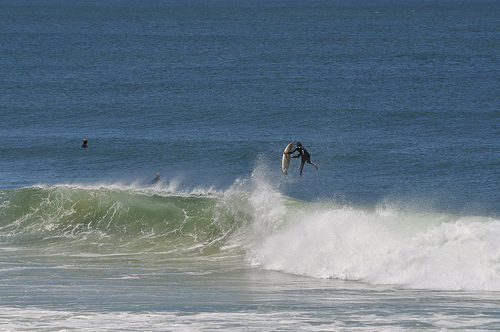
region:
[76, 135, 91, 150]
a person in the ocean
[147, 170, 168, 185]
a person in the ocean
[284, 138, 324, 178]
a person in the air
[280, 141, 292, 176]
a white surfboard in the air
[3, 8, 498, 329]
the ocean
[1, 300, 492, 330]
some sea foam on the water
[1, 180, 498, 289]
A very large wave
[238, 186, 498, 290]
a wave crashing down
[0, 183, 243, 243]
A cresting wave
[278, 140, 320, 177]
a surfer in the air with his board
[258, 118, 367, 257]
Man in mid air with surf board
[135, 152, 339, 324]
Wave is coming to a cap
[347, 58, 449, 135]
The distance of the ocean is flat.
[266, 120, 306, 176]
Man holding a surfboard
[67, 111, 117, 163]
Man in the ocean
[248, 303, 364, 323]
white foam on the water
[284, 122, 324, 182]
Surfers legs are straight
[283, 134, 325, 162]
Man is wearing a wetsuit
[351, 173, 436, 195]
Water is spraying in the air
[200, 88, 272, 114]
Small wave in the ocean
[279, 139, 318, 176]
person on a surf board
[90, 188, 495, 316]
a tidal wave on water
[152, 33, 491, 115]
clear body of water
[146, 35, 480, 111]
body of ocean water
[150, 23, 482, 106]
body of sea salt water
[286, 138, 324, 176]
person in a wet suit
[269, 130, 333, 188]
person holding on his surf board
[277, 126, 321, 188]
person carrying a surf board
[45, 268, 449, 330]
ocean water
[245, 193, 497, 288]
splashes from a wave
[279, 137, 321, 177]
a surfer in the air with his surfboard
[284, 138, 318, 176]
A man in the air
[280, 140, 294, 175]
A white surfbaord in the air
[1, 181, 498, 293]
A large wave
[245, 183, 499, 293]
A wave crashing down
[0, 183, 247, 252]
a cresting wave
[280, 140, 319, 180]
A surfer in the air.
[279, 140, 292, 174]
A white surfboard.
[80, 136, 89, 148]
A man in the water.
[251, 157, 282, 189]
White spray from the water.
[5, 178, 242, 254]
a large wave.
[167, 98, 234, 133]
Part of the water.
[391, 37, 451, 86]
Part of the blue water.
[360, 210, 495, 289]
A white rough wave.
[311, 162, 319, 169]
The person's foot.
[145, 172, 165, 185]
A person in the water.